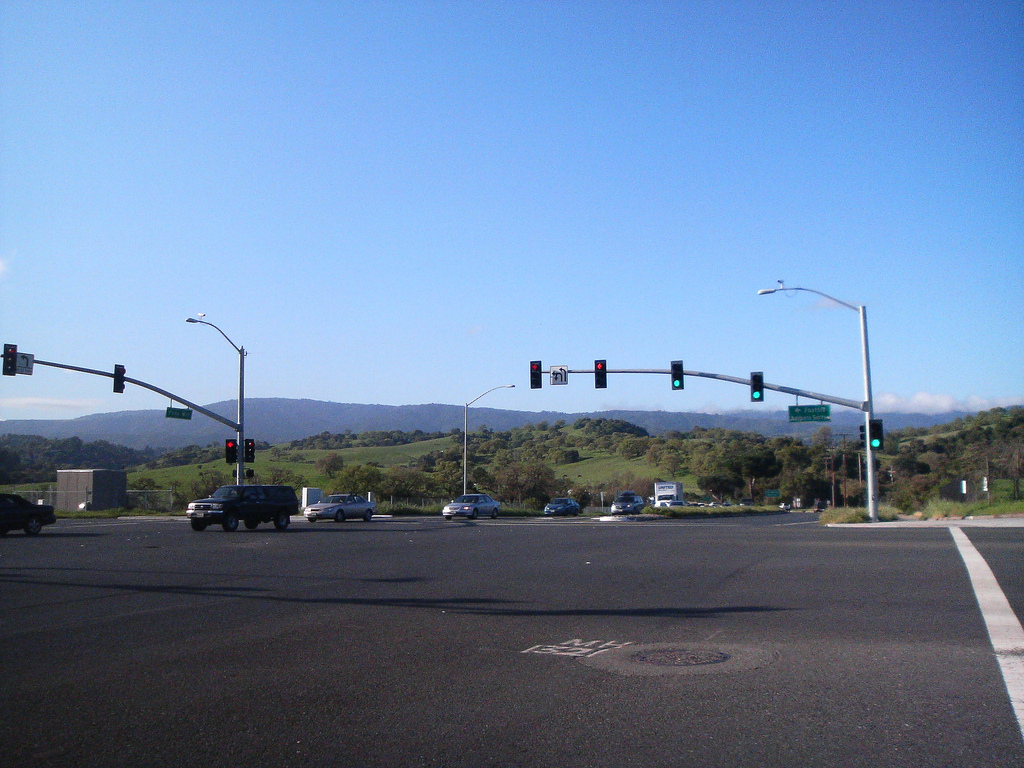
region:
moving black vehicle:
[176, 476, 303, 553]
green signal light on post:
[635, 341, 702, 415]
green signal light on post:
[732, 363, 775, 411]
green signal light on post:
[860, 401, 903, 458]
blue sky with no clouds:
[284, 160, 376, 227]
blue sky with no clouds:
[448, 156, 522, 232]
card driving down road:
[2, 493, 664, 531]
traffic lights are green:
[663, 353, 771, 402]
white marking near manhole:
[506, 626, 781, 675]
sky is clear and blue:
[3, 6, 1019, 419]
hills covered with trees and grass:
[10, 420, 1022, 515]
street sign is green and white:
[787, 395, 833, 425]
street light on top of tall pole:
[752, 277, 870, 328]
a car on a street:
[180, 471, 311, 533]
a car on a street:
[297, 491, 375, 523]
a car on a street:
[428, 481, 495, 523]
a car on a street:
[11, 490, 49, 528]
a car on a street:
[548, 491, 575, 524]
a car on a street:
[610, 480, 642, 522]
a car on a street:
[770, 499, 797, 516]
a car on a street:
[728, 499, 755, 516]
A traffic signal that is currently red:
[594, 360, 607, 390]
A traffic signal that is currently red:
[527, 358, 543, 387]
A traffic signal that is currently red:
[224, 439, 237, 462]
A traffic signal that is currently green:
[670, 360, 686, 392]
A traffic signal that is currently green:
[748, 372, 765, 404]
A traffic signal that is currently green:
[869, 420, 885, 453]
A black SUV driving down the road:
[185, 481, 300, 533]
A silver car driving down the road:
[307, 492, 377, 525]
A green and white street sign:
[789, 404, 832, 423]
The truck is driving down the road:
[140, 462, 480, 655]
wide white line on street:
[915, 527, 1005, 620]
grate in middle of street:
[618, 620, 777, 703]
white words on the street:
[517, 624, 666, 676]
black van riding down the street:
[170, 454, 317, 540]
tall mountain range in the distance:
[256, 352, 576, 463]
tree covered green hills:
[337, 433, 676, 494]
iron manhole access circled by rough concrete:
[623, 638, 742, 680]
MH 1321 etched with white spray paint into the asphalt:
[516, 615, 621, 670]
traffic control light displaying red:
[592, 350, 611, 390]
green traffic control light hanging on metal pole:
[863, 413, 887, 458]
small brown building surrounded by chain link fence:
[35, 460, 185, 512]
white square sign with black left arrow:
[15, 346, 38, 378]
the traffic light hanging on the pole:
[528, 358, 544, 388]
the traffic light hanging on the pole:
[595, 358, 608, 387]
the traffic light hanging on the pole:
[669, 360, 683, 390]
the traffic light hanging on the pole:
[750, 370, 761, 399]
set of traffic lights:
[494, 351, 906, 468]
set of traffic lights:
[503, 318, 899, 454]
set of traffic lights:
[501, 329, 912, 457]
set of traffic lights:
[509, 326, 911, 460]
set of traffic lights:
[507, 337, 906, 456]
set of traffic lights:
[516, 341, 905, 456]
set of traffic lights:
[506, 344, 918, 466]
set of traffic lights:
[528, 344, 911, 463]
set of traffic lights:
[495, 354, 920, 469]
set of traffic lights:
[510, 347, 906, 469]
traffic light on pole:
[669, 360, 689, 386]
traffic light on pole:
[593, 353, 610, 393]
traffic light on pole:
[524, 358, 545, 387]